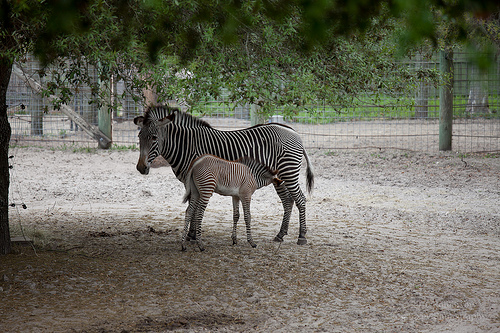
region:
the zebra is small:
[182, 150, 263, 252]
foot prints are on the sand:
[163, 259, 308, 304]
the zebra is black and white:
[142, 97, 313, 240]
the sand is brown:
[102, 245, 322, 317]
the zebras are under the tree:
[128, 96, 323, 256]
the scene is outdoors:
[8, 10, 491, 332]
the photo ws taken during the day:
[8, 5, 494, 331]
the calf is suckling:
[183, 150, 260, 254]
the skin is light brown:
[202, 160, 249, 193]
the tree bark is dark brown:
[2, 63, 19, 258]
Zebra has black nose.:
[133, 163, 156, 176]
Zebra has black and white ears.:
[125, 100, 179, 125]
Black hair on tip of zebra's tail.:
[301, 159, 331, 215]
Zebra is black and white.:
[225, 131, 272, 153]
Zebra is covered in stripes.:
[208, 132, 268, 163]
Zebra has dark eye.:
[146, 131, 163, 146]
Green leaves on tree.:
[132, 27, 180, 54]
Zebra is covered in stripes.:
[209, 168, 254, 202]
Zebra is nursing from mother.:
[221, 151, 279, 207]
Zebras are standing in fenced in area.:
[279, 60, 460, 132]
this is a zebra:
[127, 92, 317, 254]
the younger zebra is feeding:
[171, 151, 271, 250]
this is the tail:
[295, 147, 320, 187]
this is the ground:
[323, 234, 452, 331]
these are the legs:
[214, 196, 261, 248]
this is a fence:
[379, 57, 453, 144]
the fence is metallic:
[375, 57, 461, 152]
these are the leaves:
[238, 14, 359, 72]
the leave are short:
[266, 178, 313, 240]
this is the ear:
[157, 106, 179, 123]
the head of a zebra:
[117, 114, 183, 194]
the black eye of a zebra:
[143, 128, 170, 153]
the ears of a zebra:
[117, 103, 202, 128]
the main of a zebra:
[128, 81, 238, 128]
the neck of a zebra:
[166, 83, 243, 169]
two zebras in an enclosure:
[101, 73, 373, 261]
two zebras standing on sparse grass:
[94, 74, 358, 256]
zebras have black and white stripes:
[120, 88, 350, 287]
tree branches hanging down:
[9, 8, 499, 111]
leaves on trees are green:
[9, 3, 499, 130]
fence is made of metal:
[0, 53, 499, 141]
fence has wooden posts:
[3, 51, 496, 162]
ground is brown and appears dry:
[7, 106, 499, 329]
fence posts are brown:
[17, 48, 494, 161]